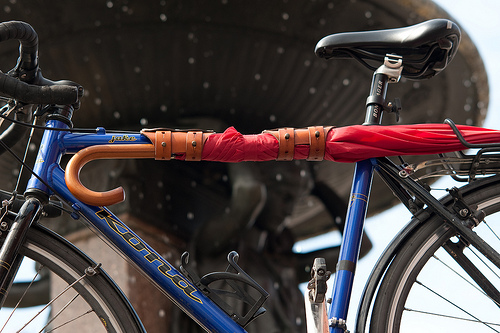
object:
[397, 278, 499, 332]
spokes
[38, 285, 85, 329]
spokes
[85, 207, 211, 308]
sticker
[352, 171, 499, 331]
wheel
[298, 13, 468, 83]
seat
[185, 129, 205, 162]
straps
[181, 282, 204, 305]
black letters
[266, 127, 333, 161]
straps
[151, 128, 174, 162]
straps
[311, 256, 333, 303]
peddle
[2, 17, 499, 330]
bike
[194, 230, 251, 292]
pedal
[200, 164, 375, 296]
statue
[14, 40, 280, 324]
blue mountain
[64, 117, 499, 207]
umbrella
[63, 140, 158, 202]
handle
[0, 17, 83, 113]
black handlebar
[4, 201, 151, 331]
wheel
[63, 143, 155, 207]
holder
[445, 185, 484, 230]
brake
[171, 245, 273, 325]
holder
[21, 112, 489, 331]
frame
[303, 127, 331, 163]
belt